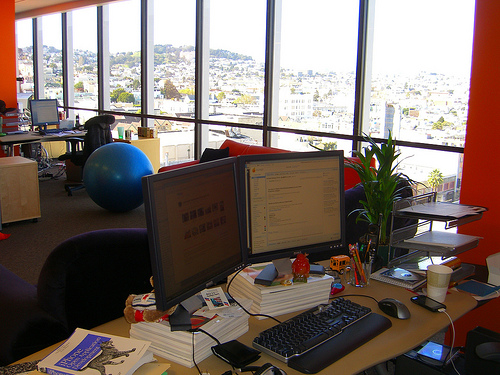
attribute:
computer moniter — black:
[25, 97, 61, 132]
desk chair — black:
[40, 221, 162, 311]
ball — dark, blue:
[81, 141, 154, 211]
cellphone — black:
[409, 292, 444, 313]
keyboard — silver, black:
[211, 280, 326, 318]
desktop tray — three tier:
[381, 189, 476, 291]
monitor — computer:
[341, 134, 412, 266]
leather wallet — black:
[189, 332, 262, 368]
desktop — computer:
[138, 131, 383, 289]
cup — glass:
[351, 255, 377, 287]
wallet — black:
[207, 336, 259, 368]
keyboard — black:
[250, 291, 375, 362]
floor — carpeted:
[3, 177, 148, 289]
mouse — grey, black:
[384, 298, 404, 325]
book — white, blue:
[31, 323, 154, 373]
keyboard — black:
[257, 303, 360, 355]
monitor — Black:
[142, 145, 237, 293]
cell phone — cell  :
[410, 289, 446, 314]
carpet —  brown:
[30, 182, 125, 228]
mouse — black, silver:
[375, 295, 409, 317]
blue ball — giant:
[80, 135, 154, 210]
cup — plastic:
[408, 252, 459, 315]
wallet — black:
[211, 337, 260, 368]